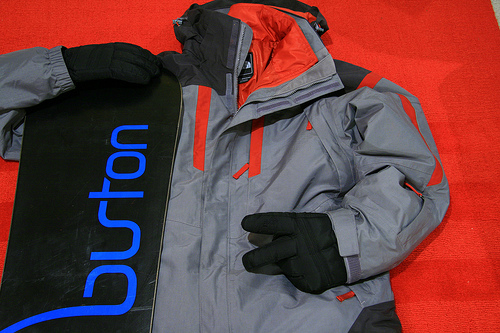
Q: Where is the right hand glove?
A: On snowboard.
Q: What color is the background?
A: Red.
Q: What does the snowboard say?
A: Burton.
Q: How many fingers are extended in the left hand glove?
A: Two.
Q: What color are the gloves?
A: Black.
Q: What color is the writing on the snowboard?
A: Blue.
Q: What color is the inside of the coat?
A: Red.